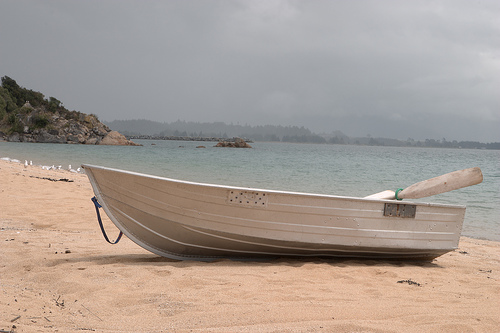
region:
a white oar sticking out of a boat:
[374, 165, 484, 199]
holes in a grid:
[226, 189, 268, 205]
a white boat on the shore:
[80, 157, 467, 255]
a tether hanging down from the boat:
[91, 197, 123, 243]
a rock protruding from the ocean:
[211, 135, 248, 149]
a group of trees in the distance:
[108, 117, 321, 142]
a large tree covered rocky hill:
[0, 76, 128, 147]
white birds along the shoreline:
[14, 159, 83, 173]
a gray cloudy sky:
[1, 0, 496, 146]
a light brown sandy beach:
[0, 159, 499, 330]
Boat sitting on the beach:
[79, 161, 484, 263]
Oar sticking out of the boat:
[354, 165, 486, 200]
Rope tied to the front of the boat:
[91, 193, 126, 245]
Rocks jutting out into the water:
[1, 72, 259, 147]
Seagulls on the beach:
[1, 154, 83, 176]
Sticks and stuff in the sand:
[0, 222, 101, 331]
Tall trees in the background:
[96, 116, 321, 143]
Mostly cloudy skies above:
[0, 0, 499, 143]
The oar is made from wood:
[361, 164, 486, 199]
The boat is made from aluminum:
[78, 160, 468, 264]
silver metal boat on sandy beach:
[77, 161, 467, 260]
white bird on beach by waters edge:
[4, 154, 81, 176]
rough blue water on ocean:
[328, 147, 420, 179]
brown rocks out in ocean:
[212, 138, 255, 152]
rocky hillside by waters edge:
[4, 74, 139, 144]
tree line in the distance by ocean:
[115, 122, 315, 137]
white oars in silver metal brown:
[340, 167, 482, 205]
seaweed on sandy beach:
[28, 174, 74, 184]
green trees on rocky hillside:
[5, 79, 65, 109]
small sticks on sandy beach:
[21, 298, 69, 331]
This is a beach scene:
[1, 0, 498, 331]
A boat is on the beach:
[78, 160, 471, 265]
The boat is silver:
[79, 160, 468, 265]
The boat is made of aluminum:
[80, 162, 470, 262]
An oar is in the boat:
[364, 163, 486, 203]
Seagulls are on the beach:
[19, 156, 82, 172]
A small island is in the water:
[212, 134, 254, 151]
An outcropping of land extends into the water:
[0, 72, 146, 149]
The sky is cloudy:
[1, 0, 498, 76]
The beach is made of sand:
[0, 157, 498, 331]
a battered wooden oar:
[372, 163, 489, 198]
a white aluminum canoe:
[70, 160, 470, 266]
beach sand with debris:
[17, 255, 129, 320]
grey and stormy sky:
[2, 4, 495, 112]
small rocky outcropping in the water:
[179, 134, 264, 154]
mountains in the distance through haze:
[109, 115, 499, 151]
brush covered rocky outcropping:
[2, 76, 119, 151]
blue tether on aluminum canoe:
[86, 190, 139, 250]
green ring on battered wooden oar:
[389, 180, 408, 201]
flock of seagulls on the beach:
[4, 151, 84, 179]